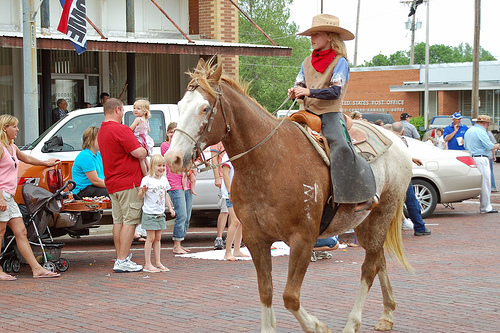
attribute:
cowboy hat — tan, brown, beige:
[298, 13, 357, 41]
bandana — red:
[310, 50, 338, 74]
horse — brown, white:
[164, 55, 413, 331]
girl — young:
[287, 13, 379, 213]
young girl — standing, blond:
[139, 154, 179, 273]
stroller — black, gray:
[0, 178, 71, 272]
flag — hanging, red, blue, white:
[55, 1, 89, 57]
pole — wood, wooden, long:
[21, 1, 37, 140]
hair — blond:
[385, 208, 415, 275]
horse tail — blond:
[387, 209, 416, 278]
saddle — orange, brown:
[290, 112, 371, 159]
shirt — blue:
[462, 124, 495, 157]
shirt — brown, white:
[220, 154, 234, 201]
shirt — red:
[97, 120, 142, 196]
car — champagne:
[412, 135, 481, 217]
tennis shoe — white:
[110, 258, 145, 272]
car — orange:
[16, 160, 111, 239]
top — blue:
[71, 148, 104, 195]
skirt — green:
[140, 214, 168, 232]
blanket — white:
[174, 242, 289, 263]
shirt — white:
[139, 174, 172, 216]